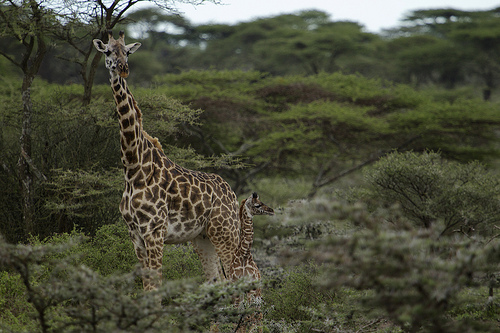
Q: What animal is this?
A: Giraffe.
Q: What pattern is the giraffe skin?
A: Spotted.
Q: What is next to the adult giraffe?
A: Baby giraffe.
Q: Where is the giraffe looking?
A: Toward the camera.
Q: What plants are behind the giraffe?
A: Trees.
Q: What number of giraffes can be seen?
A: Two.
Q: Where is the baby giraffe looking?
A: Away from the camera.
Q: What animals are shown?
A: Adult and baby giraffe.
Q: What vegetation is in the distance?
A: Trees.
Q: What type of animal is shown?
A: Giraffe.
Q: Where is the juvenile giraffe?
A: In front of the adult.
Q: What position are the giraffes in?
A: Standing.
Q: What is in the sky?
A: Clouds.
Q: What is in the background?
A: Trees.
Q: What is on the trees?
A: Leaves.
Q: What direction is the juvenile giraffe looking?
A: Right.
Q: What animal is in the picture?
A: A giraffe.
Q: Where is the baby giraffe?
A: Near the mother.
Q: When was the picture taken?
A: During the daytime.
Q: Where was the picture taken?
A: In wilderness.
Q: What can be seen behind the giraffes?
A: Trees and bushes.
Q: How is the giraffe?
A: Tall and muscular.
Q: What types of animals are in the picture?
A: Giraffes.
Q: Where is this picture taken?
A: In a forest.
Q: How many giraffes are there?
A: Two.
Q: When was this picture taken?
A: During the day.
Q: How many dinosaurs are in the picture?
A: Zero.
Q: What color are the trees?
A: Green.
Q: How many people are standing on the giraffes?
A: Zero.